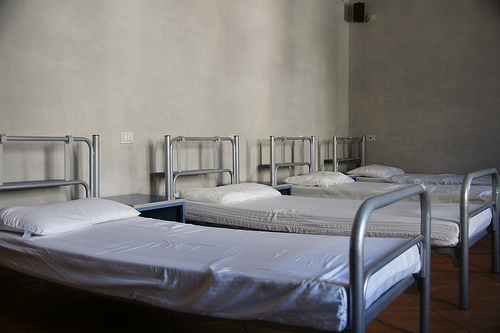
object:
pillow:
[281, 170, 356, 187]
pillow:
[0, 197, 141, 237]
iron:
[349, 183, 431, 333]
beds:
[0, 134, 434, 333]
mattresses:
[172, 183, 493, 248]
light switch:
[120, 130, 134, 144]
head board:
[333, 134, 368, 172]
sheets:
[0, 216, 423, 333]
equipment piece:
[353, 2, 367, 24]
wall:
[348, 0, 497, 177]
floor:
[414, 279, 487, 325]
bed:
[269, 135, 499, 205]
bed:
[326, 134, 500, 186]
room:
[0, 0, 497, 333]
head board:
[270, 135, 317, 186]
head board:
[0, 134, 100, 200]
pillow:
[345, 163, 406, 179]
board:
[164, 135, 239, 202]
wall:
[0, 0, 348, 210]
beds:
[164, 135, 500, 311]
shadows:
[147, 140, 165, 196]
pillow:
[173, 183, 282, 205]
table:
[102, 193, 187, 223]